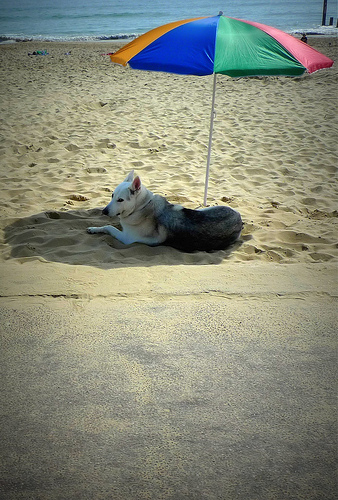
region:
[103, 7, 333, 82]
brightly colored umbrella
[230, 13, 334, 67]
pink stripe on umbrella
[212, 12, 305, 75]
green stripe on umbrella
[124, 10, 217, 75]
blue stripe on umbrella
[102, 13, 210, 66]
yellow stripe on umbrella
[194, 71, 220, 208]
pole of the umbrella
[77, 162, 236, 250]
dog laying under umbrella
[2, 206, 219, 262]
dogs shadow in the sand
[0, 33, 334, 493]
the sand on the beach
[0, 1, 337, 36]
beach water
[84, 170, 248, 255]
black and white dog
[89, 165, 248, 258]
dog sitting under umbrella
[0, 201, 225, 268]
shadow of dog on sand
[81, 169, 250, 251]
white upper body, black lower body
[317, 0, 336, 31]
black posts in water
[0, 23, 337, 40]
white residue from waves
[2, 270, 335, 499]
concrete side walk in front of sand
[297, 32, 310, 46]
person near the water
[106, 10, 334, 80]
pink, green, blue, and orange umbrella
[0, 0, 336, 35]
view of water behind sand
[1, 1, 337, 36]
Water in the ocean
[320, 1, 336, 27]
Sticks in the water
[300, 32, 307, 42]
Person on the beach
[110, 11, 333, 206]
Umbrella on the sand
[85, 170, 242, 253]
Dog lying under the umbrella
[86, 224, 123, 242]
Leg of the dog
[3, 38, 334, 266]
Sands on the beach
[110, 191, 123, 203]
Eyes of the dog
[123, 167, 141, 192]
Ears of the dog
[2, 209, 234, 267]
Shadow of the umbrella on the sand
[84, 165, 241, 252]
dog laying in the sand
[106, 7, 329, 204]
multi-colored umbrella in sand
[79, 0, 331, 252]
German shepherd at the beach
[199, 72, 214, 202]
pole holding up the umbrella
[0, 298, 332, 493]
pavement near the sandy beach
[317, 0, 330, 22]
posts sticking out of the water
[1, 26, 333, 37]
waves coming into the shore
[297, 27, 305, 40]
person on the beach near the water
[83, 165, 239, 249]
black and white dog laying on the beach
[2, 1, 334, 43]
the water is dark blue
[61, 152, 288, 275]
dog laying on the beach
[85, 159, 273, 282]
dog is black and white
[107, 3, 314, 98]
umbrella is multi colored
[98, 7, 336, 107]
umbrella is green blue orange and pink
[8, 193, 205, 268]
shadow of umbrella on sand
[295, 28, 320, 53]
person in the background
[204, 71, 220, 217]
umbrella pole is white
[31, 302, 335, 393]
sand on the concrete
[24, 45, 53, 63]
blue object in sand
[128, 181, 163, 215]
dog is wearing a collar